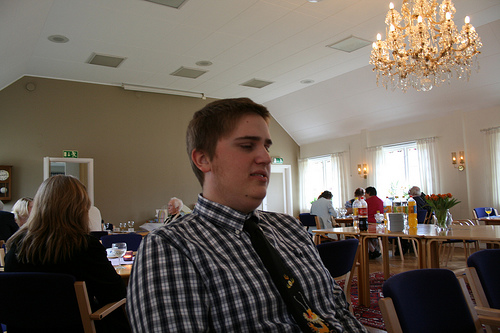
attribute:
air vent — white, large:
[169, 63, 204, 81]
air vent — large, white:
[84, 50, 127, 71]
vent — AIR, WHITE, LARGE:
[89, 41, 119, 75]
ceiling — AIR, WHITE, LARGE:
[239, 12, 270, 45]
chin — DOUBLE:
[228, 177, 272, 212]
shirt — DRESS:
[184, 242, 259, 322]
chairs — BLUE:
[411, 270, 450, 323]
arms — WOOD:
[379, 309, 399, 328]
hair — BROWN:
[200, 121, 220, 142]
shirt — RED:
[374, 195, 378, 210]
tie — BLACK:
[246, 215, 342, 330]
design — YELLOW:
[290, 296, 326, 331]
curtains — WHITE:
[386, 141, 429, 182]